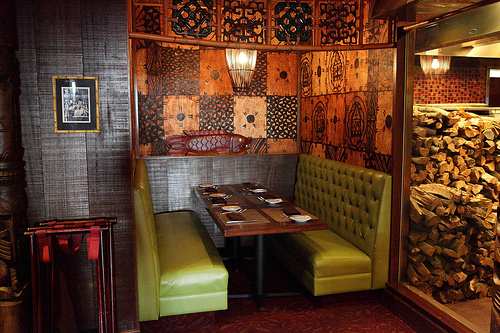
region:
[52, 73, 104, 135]
picture on the wll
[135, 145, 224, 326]
green booth in room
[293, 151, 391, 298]
green booth at table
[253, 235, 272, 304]
black pole under table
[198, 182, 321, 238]
table made of wood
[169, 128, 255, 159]
red fish on the wall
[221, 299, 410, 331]
red carpet on the ground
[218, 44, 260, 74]
light on the wall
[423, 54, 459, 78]
light coming from the ceiling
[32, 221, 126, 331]
red basket next to booth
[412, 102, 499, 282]
a pile of wood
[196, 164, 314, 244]
a table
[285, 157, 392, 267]
the green seat of the booth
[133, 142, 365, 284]
a booth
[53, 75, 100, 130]
a picture on the wall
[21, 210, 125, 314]
a red tray holder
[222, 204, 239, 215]
a white plate on the table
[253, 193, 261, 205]
silverware on the table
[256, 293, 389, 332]
the carpet under the table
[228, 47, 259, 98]
the light above the table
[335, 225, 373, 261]
a green seat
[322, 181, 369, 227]
back of the bench is green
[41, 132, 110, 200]
the wall is brown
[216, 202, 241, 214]
the plate is white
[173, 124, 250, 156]
a fish on the wall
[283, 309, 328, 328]
the floor is brown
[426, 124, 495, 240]
logs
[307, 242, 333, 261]
a shadow on the bench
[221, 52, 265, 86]
a light on the wall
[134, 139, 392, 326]
green benches in front of dining table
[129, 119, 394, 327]
seating booth in restaurant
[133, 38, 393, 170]
patterned wall paper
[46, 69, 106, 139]
framed picture on wall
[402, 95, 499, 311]
stack of wooden logs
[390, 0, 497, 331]
mirror on wall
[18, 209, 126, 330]
wooden folding tray holders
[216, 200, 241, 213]
plate on table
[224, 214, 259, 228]
utensils on top of table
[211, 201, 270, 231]
brown placemats on table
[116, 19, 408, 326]
a booth at a restaurant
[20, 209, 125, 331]
folding stands to hold trays of food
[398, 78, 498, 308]
this place has its own supply of firewood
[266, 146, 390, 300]
booth seats are green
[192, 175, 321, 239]
the table is set for six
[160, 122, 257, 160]
a fish decoration next to the table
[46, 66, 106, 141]
a picture hanging on the wall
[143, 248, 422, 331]
the carpet is a deep patterned red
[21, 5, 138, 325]
the wall has dark wood paneling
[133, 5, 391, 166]
exotic brown print wallpaper in the booth